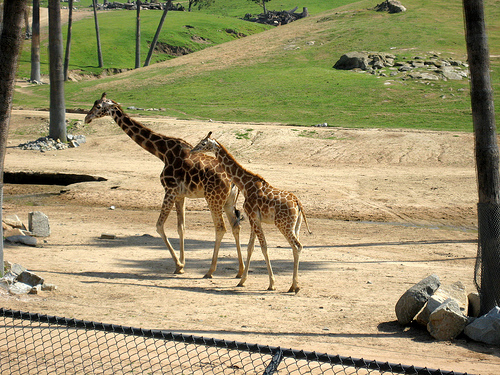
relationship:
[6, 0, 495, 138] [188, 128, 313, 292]
grass near giraffe giraffe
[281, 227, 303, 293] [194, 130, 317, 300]
giraffe leg of giraffe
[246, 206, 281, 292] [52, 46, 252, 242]
leg of giraffe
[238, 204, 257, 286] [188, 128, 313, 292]
leg of giraffe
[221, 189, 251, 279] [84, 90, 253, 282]
leg of giraffe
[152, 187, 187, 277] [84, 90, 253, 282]
leg of giraffe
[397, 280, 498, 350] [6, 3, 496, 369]
rock in zoo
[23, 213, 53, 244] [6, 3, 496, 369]
rock in zoo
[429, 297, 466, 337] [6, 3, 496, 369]
large rock in zoo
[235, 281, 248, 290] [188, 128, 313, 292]
hoof of giraffe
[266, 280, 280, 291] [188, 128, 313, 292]
hoof of giraffe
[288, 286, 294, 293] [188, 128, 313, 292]
hoof of giraffe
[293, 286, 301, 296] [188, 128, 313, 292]
hoof of giraffe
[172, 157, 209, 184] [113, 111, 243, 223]
spots decorate hide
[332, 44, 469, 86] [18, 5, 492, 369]
rocks jut out from earth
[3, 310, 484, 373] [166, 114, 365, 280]
fence near giraffe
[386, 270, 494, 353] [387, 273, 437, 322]
cluster of rock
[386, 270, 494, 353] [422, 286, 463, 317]
cluster of rock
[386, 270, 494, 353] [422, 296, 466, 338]
cluster of rock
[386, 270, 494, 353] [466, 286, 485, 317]
cluster of rock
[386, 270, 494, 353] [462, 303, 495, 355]
cluster of rock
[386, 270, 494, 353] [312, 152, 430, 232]
cluster on ground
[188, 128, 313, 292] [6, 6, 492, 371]
giraffe on field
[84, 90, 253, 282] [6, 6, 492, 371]
giraffe on field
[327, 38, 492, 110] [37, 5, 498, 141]
cluster on field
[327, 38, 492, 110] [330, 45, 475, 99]
cluster of large rock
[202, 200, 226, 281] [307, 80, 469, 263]
leg walking on field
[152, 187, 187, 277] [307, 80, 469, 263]
leg walking on field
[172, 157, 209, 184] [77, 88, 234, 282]
spots on body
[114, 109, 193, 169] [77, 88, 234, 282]
spots on body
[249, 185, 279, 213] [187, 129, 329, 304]
spots on body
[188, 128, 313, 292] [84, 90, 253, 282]
giraffe next to giraffe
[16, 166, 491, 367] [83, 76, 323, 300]
surface where walk giraffes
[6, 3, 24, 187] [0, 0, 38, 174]
trunk of tree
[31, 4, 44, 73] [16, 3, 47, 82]
trunk of tree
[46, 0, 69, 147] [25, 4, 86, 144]
tree trunk of tree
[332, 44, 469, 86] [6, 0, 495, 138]
rocks on grass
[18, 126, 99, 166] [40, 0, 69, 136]
rocks around tree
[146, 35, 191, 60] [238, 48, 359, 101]
dirt patch in grass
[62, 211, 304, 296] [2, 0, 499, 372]
shadow on ground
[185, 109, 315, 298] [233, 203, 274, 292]
giraffe has legs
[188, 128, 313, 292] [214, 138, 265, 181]
giraffe has mane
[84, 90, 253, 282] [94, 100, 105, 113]
giraffe has eye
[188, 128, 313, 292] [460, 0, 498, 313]
giraffe standing near tree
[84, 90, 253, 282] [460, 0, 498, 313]
giraffe standing near tree